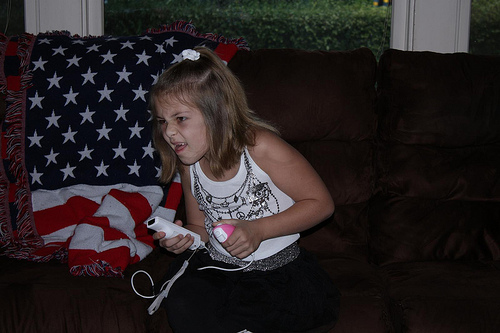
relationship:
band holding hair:
[179, 50, 200, 64] [141, 47, 248, 149]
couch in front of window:
[143, 43, 474, 299] [99, 8, 401, 65]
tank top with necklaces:
[173, 163, 293, 266] [196, 180, 259, 219]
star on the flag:
[46, 108, 62, 128] [25, 30, 234, 270]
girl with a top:
[148, 36, 341, 328] [189, 159, 292, 258]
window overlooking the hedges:
[1, 0, 499, 50] [108, 4, 392, 41]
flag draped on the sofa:
[10, 28, 242, 268] [3, 31, 498, 331]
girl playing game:
[148, 36, 341, 328] [144, 215, 233, 253]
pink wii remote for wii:
[206, 206, 247, 274] [202, 216, 260, 295]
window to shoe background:
[135, 50, 392, 60] [43, 129, 482, 166]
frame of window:
[403, 50, 464, 56] [394, 100, 441, 103]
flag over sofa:
[10, 28, 242, 268] [3, 31, 498, 331]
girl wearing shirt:
[148, 36, 341, 328] [180, 130, 308, 264]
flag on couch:
[10, 41, 178, 235] [1, 35, 496, 324]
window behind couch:
[1, 0, 499, 50] [1, 35, 496, 324]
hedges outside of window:
[105, 10, 409, 45] [97, 3, 485, 56]